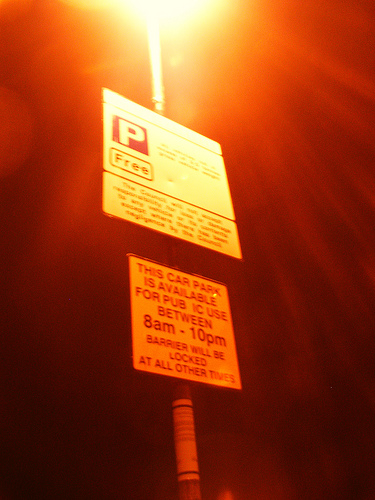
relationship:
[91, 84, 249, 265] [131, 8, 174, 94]
sign of a pole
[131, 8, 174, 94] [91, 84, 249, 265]
pole behind sign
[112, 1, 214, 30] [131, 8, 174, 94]
light on top of pole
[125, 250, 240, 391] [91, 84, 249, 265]
writing on sign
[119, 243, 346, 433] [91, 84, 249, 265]
writing on sign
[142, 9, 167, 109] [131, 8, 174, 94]
light on pole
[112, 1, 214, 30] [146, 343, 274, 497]
light on pole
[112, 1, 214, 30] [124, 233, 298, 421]
light on sign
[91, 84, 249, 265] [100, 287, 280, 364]
sign showing times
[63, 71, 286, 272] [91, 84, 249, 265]
square on sign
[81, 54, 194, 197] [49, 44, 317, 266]
p inside of square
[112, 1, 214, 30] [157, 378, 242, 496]
light on pole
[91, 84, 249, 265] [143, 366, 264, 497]
sign on pole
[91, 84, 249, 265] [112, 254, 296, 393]
sign has letters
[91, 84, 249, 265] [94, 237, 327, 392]
sign has letters